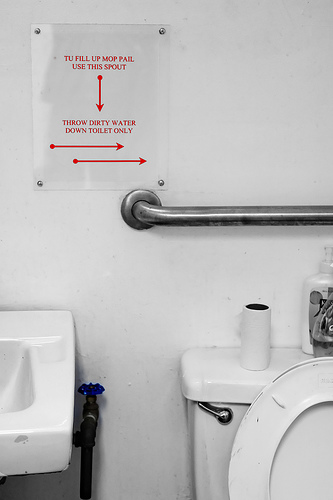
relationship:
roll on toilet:
[233, 298, 273, 375] [179, 339, 332, 496]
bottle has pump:
[302, 272, 331, 351] [321, 243, 332, 265]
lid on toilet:
[181, 344, 332, 401] [179, 339, 332, 496]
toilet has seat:
[179, 339, 332, 496] [229, 355, 332, 499]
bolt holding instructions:
[32, 27, 44, 36] [42, 51, 148, 171]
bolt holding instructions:
[155, 26, 168, 37] [42, 51, 148, 171]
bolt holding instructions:
[153, 178, 165, 188] [42, 51, 148, 171]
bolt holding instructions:
[35, 177, 47, 187] [42, 51, 148, 171]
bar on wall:
[117, 189, 332, 231] [1, 2, 332, 346]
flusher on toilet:
[194, 398, 234, 428] [179, 339, 332, 496]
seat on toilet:
[229, 355, 332, 499] [179, 339, 332, 496]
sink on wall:
[1, 302, 80, 481] [1, 2, 332, 346]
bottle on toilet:
[302, 272, 331, 351] [179, 339, 332, 496]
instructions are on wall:
[42, 51, 148, 171] [1, 2, 332, 346]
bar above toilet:
[117, 189, 332, 231] [179, 339, 332, 496]